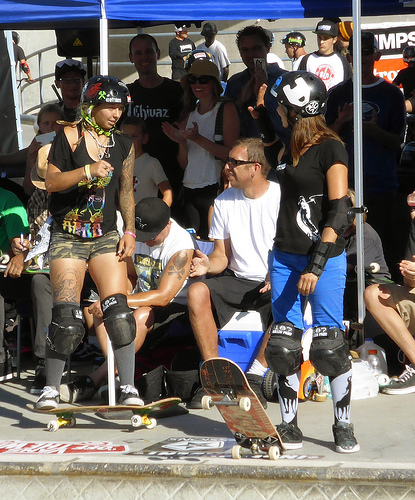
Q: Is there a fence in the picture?
A: No, there are no fences.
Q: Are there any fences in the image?
A: No, there are no fences.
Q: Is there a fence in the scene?
A: No, there are no fences.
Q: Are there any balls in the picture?
A: No, there are no balls.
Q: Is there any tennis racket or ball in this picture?
A: No, there are no balls or rackets.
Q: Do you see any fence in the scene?
A: No, there are no fences.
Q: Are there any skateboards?
A: Yes, there is a skateboard.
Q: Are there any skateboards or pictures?
A: Yes, there is a skateboard.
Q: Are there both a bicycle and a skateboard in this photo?
A: No, there is a skateboard but no bicycles.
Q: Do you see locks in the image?
A: No, there are no locks.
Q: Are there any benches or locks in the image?
A: No, there are no locks or benches.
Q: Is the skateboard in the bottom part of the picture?
A: Yes, the skateboard is in the bottom of the image.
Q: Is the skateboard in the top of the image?
A: No, the skateboard is in the bottom of the image.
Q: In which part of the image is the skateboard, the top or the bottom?
A: The skateboard is in the bottom of the image.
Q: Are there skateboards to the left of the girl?
A: Yes, there is a skateboard to the left of the girl.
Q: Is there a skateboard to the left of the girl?
A: Yes, there is a skateboard to the left of the girl.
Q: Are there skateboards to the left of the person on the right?
A: Yes, there is a skateboard to the left of the girl.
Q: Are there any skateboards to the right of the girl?
A: No, the skateboard is to the left of the girl.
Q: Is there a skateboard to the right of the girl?
A: No, the skateboard is to the left of the girl.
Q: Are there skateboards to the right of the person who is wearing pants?
A: No, the skateboard is to the left of the girl.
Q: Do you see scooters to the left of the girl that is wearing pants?
A: No, there is a skateboard to the left of the girl.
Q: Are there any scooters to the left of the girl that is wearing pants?
A: No, there is a skateboard to the left of the girl.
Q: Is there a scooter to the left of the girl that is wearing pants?
A: No, there is a skateboard to the left of the girl.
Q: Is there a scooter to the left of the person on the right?
A: No, there is a skateboard to the left of the girl.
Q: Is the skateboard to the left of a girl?
A: Yes, the skateboard is to the left of a girl.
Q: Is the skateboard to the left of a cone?
A: No, the skateboard is to the left of a girl.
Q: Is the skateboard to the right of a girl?
A: No, the skateboard is to the left of a girl.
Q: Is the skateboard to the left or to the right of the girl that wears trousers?
A: The skateboard is to the left of the girl.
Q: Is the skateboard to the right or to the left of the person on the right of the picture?
A: The skateboard is to the left of the girl.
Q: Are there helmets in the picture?
A: Yes, there is a helmet.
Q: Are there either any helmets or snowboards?
A: Yes, there is a helmet.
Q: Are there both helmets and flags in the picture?
A: No, there is a helmet but no flags.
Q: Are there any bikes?
A: No, there are no bikes.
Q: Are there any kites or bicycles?
A: No, there are no bicycles or kites.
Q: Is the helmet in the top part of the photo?
A: Yes, the helmet is in the top of the image.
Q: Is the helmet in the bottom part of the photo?
A: No, the helmet is in the top of the image.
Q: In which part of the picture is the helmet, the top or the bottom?
A: The helmet is in the top of the image.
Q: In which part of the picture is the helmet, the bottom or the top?
A: The helmet is in the top of the image.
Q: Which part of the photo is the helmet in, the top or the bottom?
A: The helmet is in the top of the image.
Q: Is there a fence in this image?
A: No, there are no fences.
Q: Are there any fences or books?
A: No, there are no fences or books.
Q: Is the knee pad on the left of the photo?
A: Yes, the knee pad is on the left of the image.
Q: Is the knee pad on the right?
A: No, the knee pad is on the left of the image.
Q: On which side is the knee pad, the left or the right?
A: The knee pad is on the left of the image.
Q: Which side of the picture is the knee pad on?
A: The knee pad is on the left of the image.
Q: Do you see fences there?
A: No, there are no fences.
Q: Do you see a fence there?
A: No, there are no fences.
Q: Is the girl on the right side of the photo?
A: Yes, the girl is on the right of the image.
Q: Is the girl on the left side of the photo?
A: No, the girl is on the right of the image.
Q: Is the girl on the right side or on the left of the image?
A: The girl is on the right of the image.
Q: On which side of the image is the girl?
A: The girl is on the right of the image.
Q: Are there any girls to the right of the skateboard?
A: Yes, there is a girl to the right of the skateboard.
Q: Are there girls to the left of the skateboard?
A: No, the girl is to the right of the skateboard.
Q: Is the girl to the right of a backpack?
A: No, the girl is to the right of the skateboard.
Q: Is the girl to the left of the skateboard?
A: No, the girl is to the right of the skateboard.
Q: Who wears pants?
A: The girl wears pants.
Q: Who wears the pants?
A: The girl wears pants.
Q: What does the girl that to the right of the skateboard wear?
A: The girl wears trousers.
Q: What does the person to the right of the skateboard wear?
A: The girl wears trousers.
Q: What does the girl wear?
A: The girl wears trousers.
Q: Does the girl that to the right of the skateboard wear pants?
A: Yes, the girl wears pants.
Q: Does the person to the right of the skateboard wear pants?
A: Yes, the girl wears pants.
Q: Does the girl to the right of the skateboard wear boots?
A: No, the girl wears pants.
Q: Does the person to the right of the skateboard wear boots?
A: No, the girl wears pants.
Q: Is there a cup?
A: No, there are no cups.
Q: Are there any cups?
A: No, there are no cups.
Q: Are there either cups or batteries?
A: No, there are no cups or batteries.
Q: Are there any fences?
A: No, there are no fences.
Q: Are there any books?
A: No, there are no books.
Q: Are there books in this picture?
A: No, there are no books.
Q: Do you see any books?
A: No, there are no books.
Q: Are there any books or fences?
A: No, there are no books or fences.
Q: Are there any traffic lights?
A: No, there are no traffic lights.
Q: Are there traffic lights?
A: No, there are no traffic lights.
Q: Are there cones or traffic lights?
A: No, there are no traffic lights or cones.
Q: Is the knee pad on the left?
A: Yes, the knee pad is on the left of the image.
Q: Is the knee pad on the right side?
A: No, the knee pad is on the left of the image.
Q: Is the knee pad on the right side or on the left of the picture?
A: The knee pad is on the left of the image.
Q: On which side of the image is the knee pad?
A: The knee pad is on the left of the image.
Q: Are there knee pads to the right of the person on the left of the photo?
A: Yes, there is a knee pad to the right of the person.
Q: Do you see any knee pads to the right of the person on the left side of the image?
A: Yes, there is a knee pad to the right of the person.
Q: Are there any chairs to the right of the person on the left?
A: No, there is a knee pad to the right of the person.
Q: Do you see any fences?
A: No, there are no fences.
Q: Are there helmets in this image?
A: Yes, there is a helmet.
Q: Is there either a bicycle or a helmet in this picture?
A: Yes, there is a helmet.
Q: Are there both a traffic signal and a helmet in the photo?
A: No, there is a helmet but no traffic lights.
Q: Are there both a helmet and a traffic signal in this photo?
A: No, there is a helmet but no traffic lights.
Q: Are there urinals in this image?
A: No, there are no urinals.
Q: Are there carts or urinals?
A: No, there are no urinals or carts.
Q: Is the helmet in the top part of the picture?
A: Yes, the helmet is in the top of the image.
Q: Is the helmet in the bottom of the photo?
A: No, the helmet is in the top of the image.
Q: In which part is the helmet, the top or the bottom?
A: The helmet is in the top of the image.